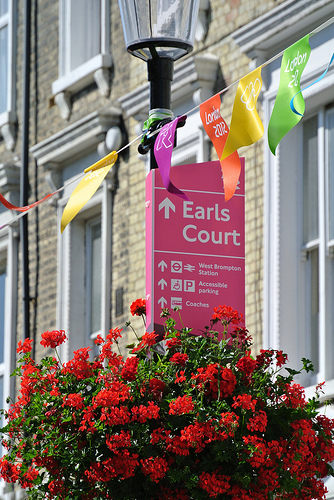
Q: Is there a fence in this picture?
A: No, there are no fences.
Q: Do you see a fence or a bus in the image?
A: No, there are no fences or buses.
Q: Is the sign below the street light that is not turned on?
A: Yes, the sign is below the lamp post.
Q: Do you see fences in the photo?
A: No, there are no fences.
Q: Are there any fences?
A: No, there are no fences.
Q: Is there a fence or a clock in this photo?
A: No, there are no fences or clocks.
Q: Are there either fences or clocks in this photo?
A: No, there are no fences or clocks.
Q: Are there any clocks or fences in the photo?
A: No, there are no fences or clocks.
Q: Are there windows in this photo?
A: Yes, there is a window.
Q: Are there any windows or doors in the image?
A: Yes, there is a window.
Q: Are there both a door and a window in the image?
A: No, there is a window but no doors.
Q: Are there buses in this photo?
A: No, there are no buses.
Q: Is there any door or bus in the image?
A: No, there are no buses or doors.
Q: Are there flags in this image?
A: Yes, there is a flag.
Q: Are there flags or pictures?
A: Yes, there is a flag.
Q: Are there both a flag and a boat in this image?
A: No, there is a flag but no boats.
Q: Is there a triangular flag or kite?
A: Yes, there is a triangular flag.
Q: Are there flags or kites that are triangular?
A: Yes, the flag is triangular.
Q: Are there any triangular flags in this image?
A: Yes, there is a triangular flag.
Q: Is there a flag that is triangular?
A: Yes, there is a flag that is triangular.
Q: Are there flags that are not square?
A: Yes, there is a triangular flag.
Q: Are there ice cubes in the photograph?
A: No, there are no ice cubes.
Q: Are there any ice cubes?
A: No, there are no ice cubes.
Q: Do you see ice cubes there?
A: No, there are no ice cubes.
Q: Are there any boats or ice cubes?
A: No, there are no ice cubes or boats.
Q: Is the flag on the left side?
A: Yes, the flag is on the left of the image.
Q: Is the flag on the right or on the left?
A: The flag is on the left of the image.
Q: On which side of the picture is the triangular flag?
A: The flag is on the left of the image.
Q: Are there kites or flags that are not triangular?
A: No, there is a flag but it is triangular.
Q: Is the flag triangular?
A: Yes, the flag is triangular.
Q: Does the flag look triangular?
A: Yes, the flag is triangular.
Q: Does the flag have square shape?
A: No, the flag is triangular.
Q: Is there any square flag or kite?
A: No, there is a flag but it is triangular.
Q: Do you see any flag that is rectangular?
A: No, there is a flag but it is triangular.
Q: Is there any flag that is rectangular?
A: No, there is a flag but it is triangular.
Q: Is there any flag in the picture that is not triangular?
A: No, there is a flag but it is triangular.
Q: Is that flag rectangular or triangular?
A: The flag is triangular.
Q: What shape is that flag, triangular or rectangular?
A: The flag is triangular.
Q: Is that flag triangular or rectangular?
A: The flag is triangular.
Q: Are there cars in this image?
A: No, there are no cars.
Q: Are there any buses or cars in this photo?
A: No, there are no cars or buses.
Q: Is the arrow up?
A: Yes, the arrow is up.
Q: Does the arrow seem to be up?
A: Yes, the arrow is up.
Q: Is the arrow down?
A: No, the arrow is up.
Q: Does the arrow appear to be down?
A: No, the arrow is up.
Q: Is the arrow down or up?
A: The arrow is up.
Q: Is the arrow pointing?
A: Yes, the arrow is pointing.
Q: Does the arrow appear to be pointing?
A: Yes, the arrow is pointing.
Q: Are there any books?
A: No, there are no books.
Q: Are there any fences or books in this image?
A: No, there are no books or fences.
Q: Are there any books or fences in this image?
A: No, there are no books or fences.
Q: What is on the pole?
A: The street light is on the pole.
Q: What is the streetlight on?
A: The streetlight is on the pole.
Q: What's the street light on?
A: The streetlight is on the pole.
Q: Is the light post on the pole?
A: Yes, the light post is on the pole.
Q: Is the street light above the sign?
A: Yes, the street light is above the sign.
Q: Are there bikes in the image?
A: No, there are no bikes.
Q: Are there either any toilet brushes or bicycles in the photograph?
A: No, there are no bicycles or toilet brushes.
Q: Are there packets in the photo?
A: No, there are no packets.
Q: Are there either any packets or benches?
A: No, there are no packets or benches.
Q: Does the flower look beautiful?
A: Yes, the flower is beautiful.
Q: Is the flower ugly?
A: No, the flower is beautiful.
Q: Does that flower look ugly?
A: No, the flower is beautiful.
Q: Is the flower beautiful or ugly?
A: The flower is beautiful.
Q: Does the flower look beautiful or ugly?
A: The flower is beautiful.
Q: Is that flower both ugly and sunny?
A: No, the flower is sunny but beautiful.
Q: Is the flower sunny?
A: Yes, the flower is sunny.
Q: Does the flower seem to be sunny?
A: Yes, the flower is sunny.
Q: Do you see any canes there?
A: No, there are no canes.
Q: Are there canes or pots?
A: No, there are no canes or pots.